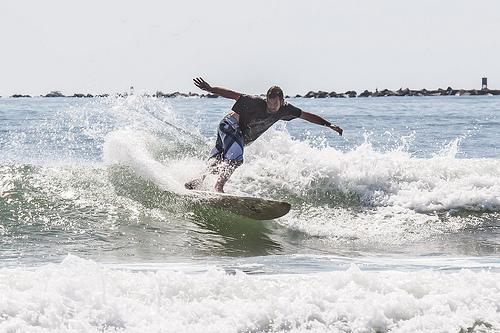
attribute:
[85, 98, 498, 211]
waves — small, white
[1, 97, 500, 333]
water — choppy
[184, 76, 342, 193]
man — wet, surfing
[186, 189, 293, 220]
surfboard — white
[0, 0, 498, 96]
sky — cloudy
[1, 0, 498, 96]
clouds — gray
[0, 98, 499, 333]
ocean — still, choppy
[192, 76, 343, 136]
arms — out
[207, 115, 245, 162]
shorts — blue, black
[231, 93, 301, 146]
shirt — black, blue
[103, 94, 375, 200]
wave — splashing, white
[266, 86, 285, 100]
hair — brown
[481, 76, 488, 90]
building — small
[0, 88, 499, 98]
shoreline — rocky